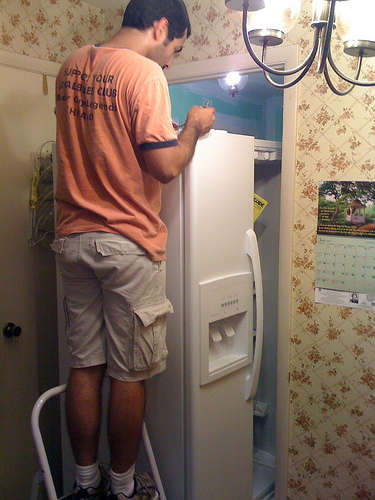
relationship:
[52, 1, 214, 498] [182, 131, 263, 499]
man removing door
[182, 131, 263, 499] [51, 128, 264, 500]
door on refrigerator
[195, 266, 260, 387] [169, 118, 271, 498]
dispenser on refrigerator door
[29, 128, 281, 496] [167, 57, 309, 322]
refrigerator stuck in doorway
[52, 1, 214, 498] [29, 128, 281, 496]
man moving refrigerator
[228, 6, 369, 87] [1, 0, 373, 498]
chandelier in kitchen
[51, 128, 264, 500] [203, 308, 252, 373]
refrigerator has ice maker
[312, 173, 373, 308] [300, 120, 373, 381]
calendar on wall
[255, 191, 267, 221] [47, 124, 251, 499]
paper in refrigerator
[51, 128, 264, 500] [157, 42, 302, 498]
refrigerator in doorway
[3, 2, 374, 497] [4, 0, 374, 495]
wallpaper on wall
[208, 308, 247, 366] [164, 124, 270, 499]
dispenser in door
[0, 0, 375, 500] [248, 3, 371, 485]
wallpaper on wall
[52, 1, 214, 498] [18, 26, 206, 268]
man wearing shirt